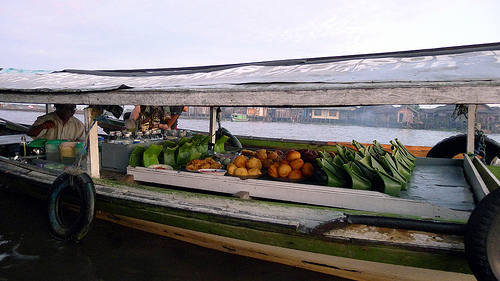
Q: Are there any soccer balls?
A: No, there are no soccer balls.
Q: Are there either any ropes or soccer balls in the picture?
A: No, there are no soccer balls or ropes.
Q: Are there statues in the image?
A: No, there are no statues.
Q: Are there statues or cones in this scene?
A: No, there are no statues or cones.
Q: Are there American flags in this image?
A: No, there are no American flags.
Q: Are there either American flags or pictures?
A: No, there are no American flags or pictures.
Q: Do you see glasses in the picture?
A: No, there are no glasses.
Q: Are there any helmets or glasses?
A: No, there are no glasses or helmets.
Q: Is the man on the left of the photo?
A: Yes, the man is on the left of the image.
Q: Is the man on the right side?
A: No, the man is on the left of the image.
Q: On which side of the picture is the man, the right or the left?
A: The man is on the left of the image.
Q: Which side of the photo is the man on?
A: The man is on the left of the image.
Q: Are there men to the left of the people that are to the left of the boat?
A: Yes, there is a man to the left of the people.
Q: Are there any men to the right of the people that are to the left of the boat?
A: No, the man is to the left of the people.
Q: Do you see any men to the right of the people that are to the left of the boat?
A: No, the man is to the left of the people.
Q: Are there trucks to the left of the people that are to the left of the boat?
A: No, there is a man to the left of the people.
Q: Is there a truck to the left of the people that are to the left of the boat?
A: No, there is a man to the left of the people.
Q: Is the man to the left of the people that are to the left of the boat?
A: Yes, the man is to the left of the people.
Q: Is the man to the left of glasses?
A: No, the man is to the left of the people.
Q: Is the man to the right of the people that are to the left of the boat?
A: No, the man is to the left of the people.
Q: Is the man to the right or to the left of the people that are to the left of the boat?
A: The man is to the left of the people.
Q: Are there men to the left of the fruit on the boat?
A: Yes, there is a man to the left of the fruit.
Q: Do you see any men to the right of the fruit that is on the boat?
A: No, the man is to the left of the fruit.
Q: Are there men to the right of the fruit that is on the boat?
A: No, the man is to the left of the fruit.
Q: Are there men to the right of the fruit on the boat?
A: No, the man is to the left of the fruit.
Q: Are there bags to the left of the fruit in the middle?
A: No, there is a man to the left of the fruit.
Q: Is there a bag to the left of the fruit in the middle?
A: No, there is a man to the left of the fruit.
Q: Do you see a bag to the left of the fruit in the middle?
A: No, there is a man to the left of the fruit.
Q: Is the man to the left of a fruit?
A: Yes, the man is to the left of a fruit.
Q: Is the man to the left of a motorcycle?
A: No, the man is to the left of a fruit.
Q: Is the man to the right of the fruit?
A: No, the man is to the left of the fruit.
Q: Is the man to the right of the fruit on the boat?
A: No, the man is to the left of the fruit.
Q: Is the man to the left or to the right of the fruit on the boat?
A: The man is to the left of the fruit.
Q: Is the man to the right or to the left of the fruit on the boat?
A: The man is to the left of the fruit.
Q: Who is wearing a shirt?
A: The man is wearing a shirt.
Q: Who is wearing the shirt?
A: The man is wearing a shirt.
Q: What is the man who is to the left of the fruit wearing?
A: The man is wearing a shirt.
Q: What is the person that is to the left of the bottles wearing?
A: The man is wearing a shirt.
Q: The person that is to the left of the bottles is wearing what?
A: The man is wearing a shirt.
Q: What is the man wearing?
A: The man is wearing a shirt.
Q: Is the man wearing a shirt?
A: Yes, the man is wearing a shirt.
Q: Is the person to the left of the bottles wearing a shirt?
A: Yes, the man is wearing a shirt.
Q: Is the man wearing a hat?
A: No, the man is wearing a shirt.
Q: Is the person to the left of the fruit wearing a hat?
A: No, the man is wearing a shirt.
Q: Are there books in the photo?
A: No, there are no books.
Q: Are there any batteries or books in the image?
A: No, there are no books or batteries.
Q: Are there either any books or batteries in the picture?
A: No, there are no books or batteries.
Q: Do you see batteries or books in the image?
A: No, there are no books or batteries.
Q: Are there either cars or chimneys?
A: No, there are no cars or chimneys.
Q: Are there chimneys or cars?
A: No, there are no cars or chimneys.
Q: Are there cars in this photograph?
A: No, there are no cars.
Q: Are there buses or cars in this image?
A: No, there are no cars or buses.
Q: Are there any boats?
A: Yes, there is a boat.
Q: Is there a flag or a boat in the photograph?
A: Yes, there is a boat.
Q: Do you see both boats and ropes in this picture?
A: No, there is a boat but no ropes.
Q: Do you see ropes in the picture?
A: No, there are no ropes.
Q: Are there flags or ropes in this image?
A: No, there are no ropes or flags.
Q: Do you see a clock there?
A: No, there are no clocks.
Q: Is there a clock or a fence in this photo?
A: No, there are no clocks or fences.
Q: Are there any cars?
A: No, there are no cars.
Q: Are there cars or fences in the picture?
A: No, there are no cars or fences.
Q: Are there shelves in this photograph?
A: No, there are no shelves.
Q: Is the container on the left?
A: Yes, the container is on the left of the image.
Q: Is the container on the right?
A: No, the container is on the left of the image.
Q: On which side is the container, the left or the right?
A: The container is on the left of the image.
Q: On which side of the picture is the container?
A: The container is on the left of the image.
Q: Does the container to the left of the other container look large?
A: Yes, the container is large.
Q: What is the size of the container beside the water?
A: The container is large.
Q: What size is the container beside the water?
A: The container is large.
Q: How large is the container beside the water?
A: The container is large.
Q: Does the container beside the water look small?
A: No, the container is large.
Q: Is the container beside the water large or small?
A: The container is large.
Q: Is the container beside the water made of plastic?
A: Yes, the container is made of plastic.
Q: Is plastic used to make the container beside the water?
A: Yes, the container is made of plastic.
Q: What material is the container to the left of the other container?
A: The container is made of plastic.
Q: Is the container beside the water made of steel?
A: No, the container is made of plastic.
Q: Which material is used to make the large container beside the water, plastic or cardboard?
A: The container is made of plastic.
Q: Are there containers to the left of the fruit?
A: Yes, there is a container to the left of the fruit.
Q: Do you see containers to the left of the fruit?
A: Yes, there is a container to the left of the fruit.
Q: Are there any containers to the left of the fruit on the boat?
A: Yes, there is a container to the left of the fruit.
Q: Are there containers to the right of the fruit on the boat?
A: No, the container is to the left of the fruit.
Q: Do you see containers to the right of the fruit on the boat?
A: No, the container is to the left of the fruit.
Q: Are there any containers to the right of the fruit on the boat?
A: No, the container is to the left of the fruit.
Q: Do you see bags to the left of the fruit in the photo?
A: No, there is a container to the left of the fruit.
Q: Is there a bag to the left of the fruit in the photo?
A: No, there is a container to the left of the fruit.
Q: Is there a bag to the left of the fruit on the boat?
A: No, there is a container to the left of the fruit.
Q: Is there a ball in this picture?
A: No, there are no balls.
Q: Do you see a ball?
A: No, there are no balls.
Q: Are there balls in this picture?
A: No, there are no balls.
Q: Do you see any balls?
A: No, there are no balls.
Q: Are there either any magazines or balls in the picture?
A: No, there are no balls or magazines.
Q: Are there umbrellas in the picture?
A: No, there are no umbrellas.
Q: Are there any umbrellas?
A: No, there are no umbrellas.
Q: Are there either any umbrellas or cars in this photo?
A: No, there are no umbrellas or cars.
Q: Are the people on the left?
A: Yes, the people are on the left of the image.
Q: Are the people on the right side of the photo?
A: No, the people are on the left of the image.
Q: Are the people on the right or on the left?
A: The people are on the left of the image.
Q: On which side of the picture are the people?
A: The people are on the left of the image.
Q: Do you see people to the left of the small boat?
A: Yes, there are people to the left of the boat.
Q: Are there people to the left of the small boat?
A: Yes, there are people to the left of the boat.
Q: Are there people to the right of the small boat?
A: No, the people are to the left of the boat.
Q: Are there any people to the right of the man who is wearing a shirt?
A: Yes, there are people to the right of the man.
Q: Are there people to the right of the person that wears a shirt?
A: Yes, there are people to the right of the man.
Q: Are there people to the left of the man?
A: No, the people are to the right of the man.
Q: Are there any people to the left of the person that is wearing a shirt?
A: No, the people are to the right of the man.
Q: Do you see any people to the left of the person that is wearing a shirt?
A: No, the people are to the right of the man.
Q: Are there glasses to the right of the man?
A: No, there are people to the right of the man.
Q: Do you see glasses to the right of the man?
A: No, there are people to the right of the man.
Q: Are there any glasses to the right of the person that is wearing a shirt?
A: No, there are people to the right of the man.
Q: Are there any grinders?
A: No, there are no grinders.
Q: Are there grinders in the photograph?
A: No, there are no grinders.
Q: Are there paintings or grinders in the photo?
A: No, there are no grinders or paintings.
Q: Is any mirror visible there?
A: No, there are no mirrors.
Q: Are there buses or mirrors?
A: No, there are no mirrors or buses.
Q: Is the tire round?
A: Yes, the tire is round.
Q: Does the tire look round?
A: Yes, the tire is round.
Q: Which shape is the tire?
A: The tire is round.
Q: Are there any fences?
A: No, there are no fences.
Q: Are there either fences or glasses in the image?
A: No, there are no fences or glasses.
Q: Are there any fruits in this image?
A: Yes, there is a fruit.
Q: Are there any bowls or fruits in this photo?
A: Yes, there is a fruit.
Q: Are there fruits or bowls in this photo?
A: Yes, there is a fruit.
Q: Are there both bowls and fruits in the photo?
A: Yes, there are both a fruit and a bowl.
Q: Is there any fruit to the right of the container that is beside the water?
A: Yes, there is a fruit to the right of the container.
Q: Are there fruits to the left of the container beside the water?
A: No, the fruit is to the right of the container.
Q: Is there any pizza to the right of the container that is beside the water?
A: No, there is a fruit to the right of the container.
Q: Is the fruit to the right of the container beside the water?
A: Yes, the fruit is to the right of the container.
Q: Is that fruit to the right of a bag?
A: No, the fruit is to the right of the container.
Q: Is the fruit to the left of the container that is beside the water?
A: No, the fruit is to the right of the container.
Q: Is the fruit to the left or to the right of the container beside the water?
A: The fruit is to the right of the container.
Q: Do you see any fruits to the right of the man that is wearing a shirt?
A: Yes, there is a fruit to the right of the man.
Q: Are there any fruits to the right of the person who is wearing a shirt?
A: Yes, there is a fruit to the right of the man.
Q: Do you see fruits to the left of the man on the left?
A: No, the fruit is to the right of the man.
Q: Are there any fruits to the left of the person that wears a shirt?
A: No, the fruit is to the right of the man.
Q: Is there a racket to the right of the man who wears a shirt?
A: No, there is a fruit to the right of the man.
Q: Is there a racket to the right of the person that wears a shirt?
A: No, there is a fruit to the right of the man.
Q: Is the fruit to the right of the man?
A: Yes, the fruit is to the right of the man.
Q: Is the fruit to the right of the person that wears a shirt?
A: Yes, the fruit is to the right of the man.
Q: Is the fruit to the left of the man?
A: No, the fruit is to the right of the man.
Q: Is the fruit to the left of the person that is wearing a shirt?
A: No, the fruit is to the right of the man.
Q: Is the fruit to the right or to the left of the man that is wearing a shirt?
A: The fruit is to the right of the man.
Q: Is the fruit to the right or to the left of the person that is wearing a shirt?
A: The fruit is to the right of the man.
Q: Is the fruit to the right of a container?
A: Yes, the fruit is to the right of a container.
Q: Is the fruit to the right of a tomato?
A: No, the fruit is to the right of a container.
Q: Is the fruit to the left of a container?
A: No, the fruit is to the right of a container.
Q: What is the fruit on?
A: The fruit is on the boat.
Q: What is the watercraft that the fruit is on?
A: The watercraft is a boat.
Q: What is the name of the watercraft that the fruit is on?
A: The watercraft is a boat.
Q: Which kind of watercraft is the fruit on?
A: The fruit is on the boat.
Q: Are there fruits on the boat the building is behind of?
A: Yes, there is a fruit on the boat.